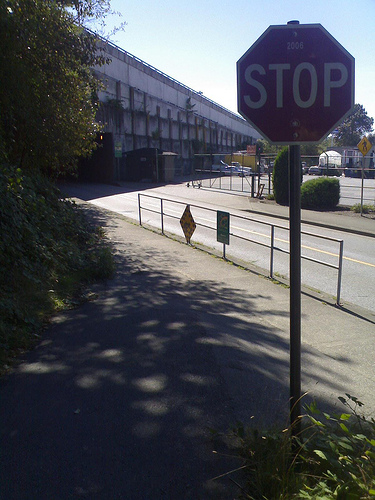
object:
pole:
[289, 139, 302, 466]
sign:
[233, 22, 357, 146]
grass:
[1, 200, 113, 377]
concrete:
[1, 207, 373, 499]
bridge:
[73, 19, 271, 178]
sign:
[353, 135, 373, 158]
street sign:
[177, 206, 198, 242]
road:
[60, 177, 374, 319]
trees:
[2, 1, 119, 175]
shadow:
[5, 214, 353, 499]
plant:
[208, 380, 374, 498]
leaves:
[338, 411, 354, 423]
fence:
[135, 193, 344, 305]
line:
[137, 180, 373, 267]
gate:
[189, 150, 278, 197]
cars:
[215, 157, 248, 174]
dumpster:
[122, 143, 181, 183]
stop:
[243, 60, 351, 117]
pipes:
[128, 86, 139, 159]